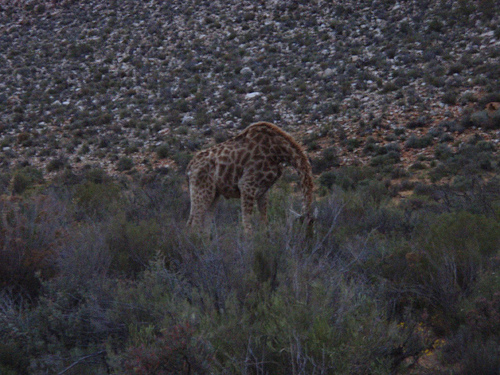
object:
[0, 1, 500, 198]
landscape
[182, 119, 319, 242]
giraffe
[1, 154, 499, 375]
grass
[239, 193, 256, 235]
leg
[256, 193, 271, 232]
leg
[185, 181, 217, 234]
leg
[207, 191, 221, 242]
leg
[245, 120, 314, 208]
mane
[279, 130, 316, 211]
neck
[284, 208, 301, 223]
ear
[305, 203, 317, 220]
ear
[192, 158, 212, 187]
bump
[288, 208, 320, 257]
head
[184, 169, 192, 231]
tail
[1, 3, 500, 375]
field